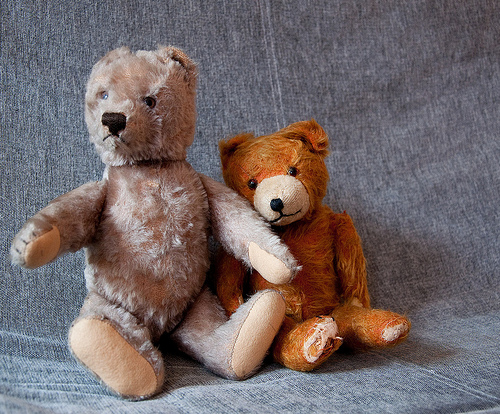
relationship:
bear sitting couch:
[8, 44, 301, 402] [3, 6, 484, 409]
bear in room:
[8, 44, 301, 402] [4, 9, 484, 402]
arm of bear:
[6, 180, 92, 267] [2, 44, 294, 400]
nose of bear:
[268, 194, 282, 218] [218, 117, 368, 276]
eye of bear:
[96, 87, 108, 102] [2, 44, 294, 400]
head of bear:
[83, 44, 196, 164] [2, 44, 294, 400]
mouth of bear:
[98, 132, 130, 154] [65, 31, 213, 171]